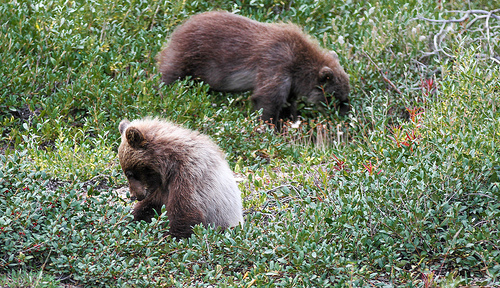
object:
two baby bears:
[115, 10, 352, 233]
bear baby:
[112, 116, 246, 236]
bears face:
[307, 57, 352, 125]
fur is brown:
[157, 11, 346, 121]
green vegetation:
[0, 1, 499, 286]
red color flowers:
[386, 78, 435, 153]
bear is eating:
[155, 11, 351, 131]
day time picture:
[1, 0, 500, 287]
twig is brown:
[428, 11, 497, 64]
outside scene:
[2, 2, 497, 284]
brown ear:
[122, 122, 142, 144]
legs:
[124, 198, 204, 244]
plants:
[295, 109, 371, 155]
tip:
[364, 157, 378, 174]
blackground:
[4, 5, 146, 40]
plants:
[80, 103, 268, 263]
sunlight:
[167, 114, 236, 203]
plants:
[330, 200, 450, 259]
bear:
[158, 10, 352, 127]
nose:
[315, 110, 353, 127]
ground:
[235, 117, 465, 210]